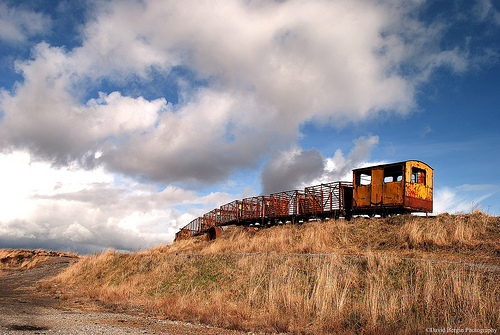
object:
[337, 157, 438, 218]
train car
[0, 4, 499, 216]
sky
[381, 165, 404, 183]
window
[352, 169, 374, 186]
window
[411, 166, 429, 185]
window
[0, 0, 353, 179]
cloud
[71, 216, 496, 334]
field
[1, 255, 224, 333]
road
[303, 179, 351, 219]
train cars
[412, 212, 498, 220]
tracks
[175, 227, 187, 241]
wood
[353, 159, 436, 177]
roof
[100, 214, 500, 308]
hill